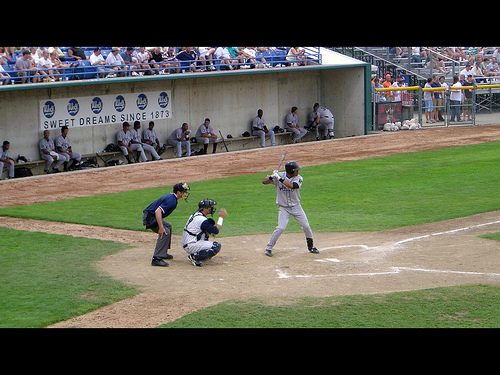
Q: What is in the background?
A: The fans.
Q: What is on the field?
A: The baseball players.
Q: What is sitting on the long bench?
A: The baseball players.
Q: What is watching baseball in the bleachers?
A: The spectators.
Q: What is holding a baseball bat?
A: The man.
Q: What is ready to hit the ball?
A: The baseball player.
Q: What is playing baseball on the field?
A: The man.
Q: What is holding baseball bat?
A: The man.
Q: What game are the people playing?
A: Baseball.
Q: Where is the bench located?
A: In the dugout.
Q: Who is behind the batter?
A: The catcher.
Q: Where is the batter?
A: At home plate.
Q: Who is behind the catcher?
A: The umpire.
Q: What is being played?
A: Baseball.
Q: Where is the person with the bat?
A: In the batter's box.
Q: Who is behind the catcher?
A: The umpire.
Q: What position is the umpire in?
A: Hunched bent knees.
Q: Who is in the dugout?
A: Baseball players.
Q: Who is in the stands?
A: Baseball spectators.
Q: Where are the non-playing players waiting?
A: In the dugout.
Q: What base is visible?
A: Home base.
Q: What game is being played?
A: Baseball.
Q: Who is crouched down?
A: The catcher.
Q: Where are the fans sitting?
A: In the stands.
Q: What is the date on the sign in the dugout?
A: 1973.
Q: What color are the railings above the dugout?
A: Blue.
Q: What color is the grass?
A: Green.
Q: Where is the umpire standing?
A: Behind the catcher.